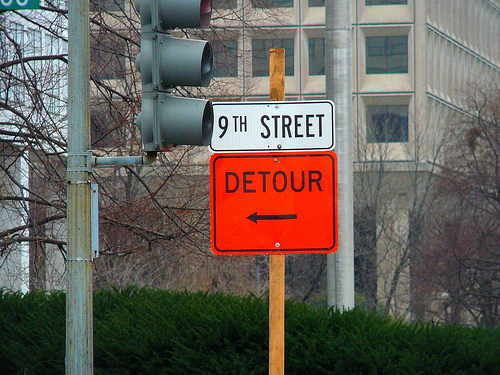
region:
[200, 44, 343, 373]
traffic signs on a wooden stick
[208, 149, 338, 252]
a red detour traffic sign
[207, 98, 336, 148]
a white street name steel plate sign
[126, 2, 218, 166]
a traffic red and green signal light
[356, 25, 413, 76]
windows of a building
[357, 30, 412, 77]
reflections coming off from window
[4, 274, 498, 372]
a bunch of green bushes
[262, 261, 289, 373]
a wooden poll stick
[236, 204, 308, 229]
an arrow on a red sign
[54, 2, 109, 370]
a metal steel poll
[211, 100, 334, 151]
the sign is white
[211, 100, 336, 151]
the sign reads 9th street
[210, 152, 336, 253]
the street sign is red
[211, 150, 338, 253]
the street sign is square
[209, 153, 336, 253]
the street sign reads detour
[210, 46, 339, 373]
the street signs are attached to a wood pole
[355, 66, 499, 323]
the trees are dead and leafless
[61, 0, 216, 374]
the stop light is gray in color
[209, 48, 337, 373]
the wooden pole supports two signs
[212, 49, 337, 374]
the pole holding the street signs is made of wood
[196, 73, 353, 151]
white 9th Street sign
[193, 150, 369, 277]
temporary orange detour sign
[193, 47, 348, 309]
temporary 9th street detour sign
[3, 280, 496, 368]
bushes near a road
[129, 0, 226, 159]
gray traffic light with red illuminated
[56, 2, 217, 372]
gray traffic light on a rusty pole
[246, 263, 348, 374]
wooden stick for holding signs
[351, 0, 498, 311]
Concrete office building with windows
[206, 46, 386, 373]
9th Street detour sign on a wood stick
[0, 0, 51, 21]
green street sign just out of frame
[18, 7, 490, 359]
a scene in a city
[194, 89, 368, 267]
a orange and white sign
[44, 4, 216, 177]
a gray traffic light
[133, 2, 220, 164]
three different colored traffic lights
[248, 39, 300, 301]
a wooden pole on the sign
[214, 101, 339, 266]
this is a detour sign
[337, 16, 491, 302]
a building in the background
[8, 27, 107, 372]
a light pole on the street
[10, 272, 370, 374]
green bushes in the background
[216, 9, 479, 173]
windows on a building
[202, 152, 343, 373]
a red traffic street sign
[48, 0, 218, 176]
a traffic signal light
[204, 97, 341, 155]
street name sign on poll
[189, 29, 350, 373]
a traffic sign on poll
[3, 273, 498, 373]
a bunch of bushes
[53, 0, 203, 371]
traffic signal light on a poll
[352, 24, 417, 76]
a building's window reflection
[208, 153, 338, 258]
a red detour signal sign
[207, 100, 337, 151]
a white street name sign